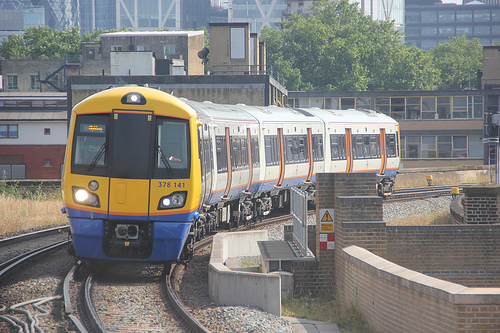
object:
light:
[75, 190, 87, 201]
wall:
[341, 224, 499, 287]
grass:
[0, 187, 64, 233]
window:
[406, 104, 421, 119]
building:
[66, 75, 286, 104]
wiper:
[89, 142, 108, 170]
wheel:
[199, 227, 206, 240]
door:
[345, 128, 352, 172]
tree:
[262, 0, 398, 91]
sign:
[321, 210, 333, 221]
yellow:
[61, 86, 202, 215]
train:
[62, 87, 401, 263]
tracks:
[166, 265, 210, 333]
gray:
[179, 99, 395, 122]